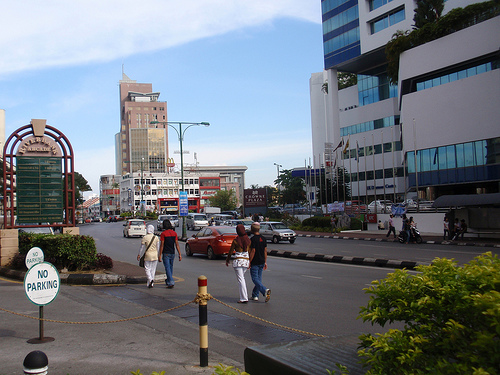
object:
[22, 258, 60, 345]
sign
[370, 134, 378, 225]
flag pole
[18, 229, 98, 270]
bush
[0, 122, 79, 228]
sign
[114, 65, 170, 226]
building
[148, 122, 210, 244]
street lights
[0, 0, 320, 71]
cloud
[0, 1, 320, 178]
sky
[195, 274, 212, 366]
pole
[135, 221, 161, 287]
woman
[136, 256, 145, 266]
purse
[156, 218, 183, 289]
person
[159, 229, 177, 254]
jacket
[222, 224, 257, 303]
woman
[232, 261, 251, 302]
pants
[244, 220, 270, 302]
man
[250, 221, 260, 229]
cap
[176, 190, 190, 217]
street sign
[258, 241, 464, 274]
divider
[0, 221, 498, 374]
street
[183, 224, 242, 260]
car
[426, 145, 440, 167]
flags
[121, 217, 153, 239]
vehicle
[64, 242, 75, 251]
leaves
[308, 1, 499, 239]
building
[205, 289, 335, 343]
ropes